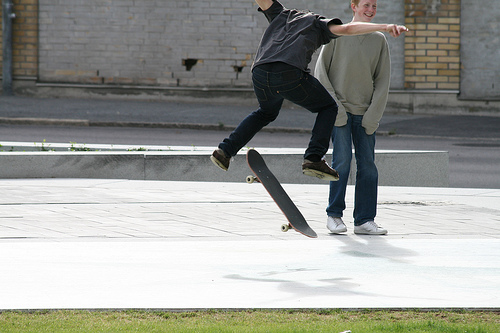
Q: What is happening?
A: Skateboarding.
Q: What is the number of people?
A: Two.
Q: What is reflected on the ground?
A: The boys' shadows.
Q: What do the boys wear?
A: Long slacks.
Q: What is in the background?
A: A brick wall.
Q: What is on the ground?
A: Shadows.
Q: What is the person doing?
A: Skating.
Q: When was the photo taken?
A: During the daytime.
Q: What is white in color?
A: The street.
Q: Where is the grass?
A: Next to the pavement.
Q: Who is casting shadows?
A: The boys.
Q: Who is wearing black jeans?
A: The boy.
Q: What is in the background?
A: Bricks.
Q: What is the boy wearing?
A: Black t-shirt.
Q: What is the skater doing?
A: A trick.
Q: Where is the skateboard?
A: In the air.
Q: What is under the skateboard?
A: Sidewalk.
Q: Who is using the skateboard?
A: The male in black pants.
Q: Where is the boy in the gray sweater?
A: In front of the boy on the skateboard.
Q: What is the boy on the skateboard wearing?
A: A gray shirt and black jeans.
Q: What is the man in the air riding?
A: A skateboard.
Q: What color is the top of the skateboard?
A: Black.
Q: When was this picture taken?
A: Daytime.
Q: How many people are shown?
A: Two.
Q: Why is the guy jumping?
A: To do a skateboard trick.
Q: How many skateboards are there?
A: One.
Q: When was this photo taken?
A: Daytime.